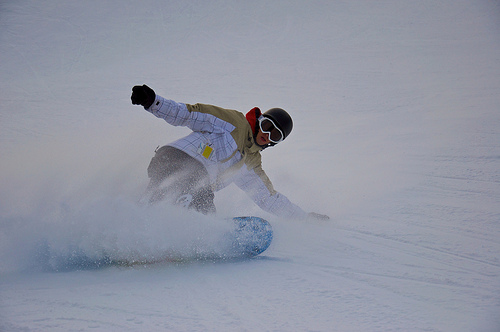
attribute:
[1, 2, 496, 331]
snow — white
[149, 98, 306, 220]
jacket — white, yellow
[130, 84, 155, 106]
glove — black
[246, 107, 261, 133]
hood — red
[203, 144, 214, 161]
tag — yellow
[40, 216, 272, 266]
snowboard — blue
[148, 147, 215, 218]
pants — black